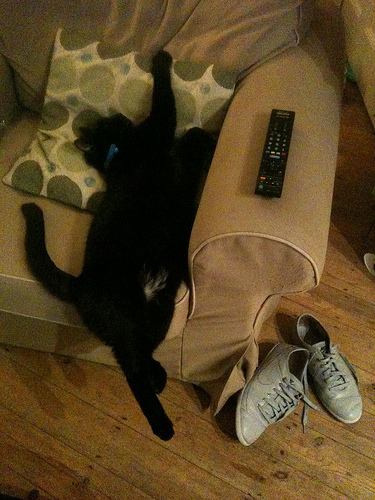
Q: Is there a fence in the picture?
A: No, there are no fences.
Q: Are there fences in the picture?
A: No, there are no fences.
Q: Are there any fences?
A: No, there are no fences.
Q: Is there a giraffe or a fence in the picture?
A: No, there are no fences or giraffes.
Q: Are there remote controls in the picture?
A: Yes, there is a remote control.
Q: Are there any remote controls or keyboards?
A: Yes, there is a remote control.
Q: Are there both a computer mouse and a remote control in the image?
A: No, there is a remote control but no computer mice.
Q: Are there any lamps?
A: No, there are no lamps.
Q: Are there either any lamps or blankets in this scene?
A: No, there are no lamps or blankets.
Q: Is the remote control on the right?
A: Yes, the remote control is on the right of the image.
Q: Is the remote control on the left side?
A: No, the remote control is on the right of the image.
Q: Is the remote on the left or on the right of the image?
A: The remote is on the right of the image.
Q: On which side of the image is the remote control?
A: The remote control is on the right of the image.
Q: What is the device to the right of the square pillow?
A: The device is a remote control.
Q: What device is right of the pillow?
A: The device is a remote control.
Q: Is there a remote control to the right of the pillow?
A: Yes, there is a remote control to the right of the pillow.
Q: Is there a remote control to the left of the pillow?
A: No, the remote control is to the right of the pillow.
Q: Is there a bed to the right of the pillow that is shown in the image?
A: No, there is a remote control to the right of the pillow.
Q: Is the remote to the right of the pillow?
A: Yes, the remote is to the right of the pillow.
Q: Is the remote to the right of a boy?
A: No, the remote is to the right of the pillow.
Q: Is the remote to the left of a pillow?
A: No, the remote is to the right of a pillow.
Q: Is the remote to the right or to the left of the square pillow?
A: The remote is to the right of the pillow.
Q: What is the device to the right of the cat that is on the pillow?
A: The device is a remote control.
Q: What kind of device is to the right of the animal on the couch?
A: The device is a remote control.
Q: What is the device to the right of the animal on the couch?
A: The device is a remote control.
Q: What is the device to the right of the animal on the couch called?
A: The device is a remote control.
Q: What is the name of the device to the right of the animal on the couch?
A: The device is a remote control.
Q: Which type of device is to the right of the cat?
A: The device is a remote control.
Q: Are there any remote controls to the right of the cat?
A: Yes, there is a remote control to the right of the cat.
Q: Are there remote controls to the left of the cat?
A: No, the remote control is to the right of the cat.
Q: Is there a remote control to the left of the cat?
A: No, the remote control is to the right of the cat.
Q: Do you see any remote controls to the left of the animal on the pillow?
A: No, the remote control is to the right of the cat.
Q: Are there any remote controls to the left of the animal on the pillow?
A: No, the remote control is to the right of the cat.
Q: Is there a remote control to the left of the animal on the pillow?
A: No, the remote control is to the right of the cat.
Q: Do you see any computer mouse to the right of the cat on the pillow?
A: No, there is a remote control to the right of the cat.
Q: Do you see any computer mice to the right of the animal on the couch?
A: No, there is a remote control to the right of the cat.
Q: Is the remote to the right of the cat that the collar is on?
A: Yes, the remote is to the right of the cat.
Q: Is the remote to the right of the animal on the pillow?
A: Yes, the remote is to the right of the cat.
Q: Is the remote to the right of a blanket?
A: No, the remote is to the right of the cat.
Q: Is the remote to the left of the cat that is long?
A: No, the remote is to the right of the cat.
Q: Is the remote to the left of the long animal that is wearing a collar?
A: No, the remote is to the right of the cat.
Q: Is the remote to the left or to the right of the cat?
A: The remote is to the right of the cat.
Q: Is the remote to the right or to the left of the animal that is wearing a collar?
A: The remote is to the right of the cat.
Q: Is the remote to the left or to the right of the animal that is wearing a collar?
A: The remote is to the right of the cat.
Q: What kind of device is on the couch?
A: The device is a remote control.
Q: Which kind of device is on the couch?
A: The device is a remote control.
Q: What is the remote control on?
A: The remote control is on the couch.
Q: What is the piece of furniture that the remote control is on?
A: The piece of furniture is a couch.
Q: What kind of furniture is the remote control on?
A: The remote control is on the couch.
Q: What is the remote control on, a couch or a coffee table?
A: The remote control is on a couch.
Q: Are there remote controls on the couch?
A: Yes, there is a remote control on the couch.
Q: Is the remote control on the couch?
A: Yes, the remote control is on the couch.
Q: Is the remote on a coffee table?
A: No, the remote is on the couch.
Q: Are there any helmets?
A: No, there are no helmets.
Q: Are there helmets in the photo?
A: No, there are no helmets.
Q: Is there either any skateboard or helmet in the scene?
A: No, there are no helmets or skateboards.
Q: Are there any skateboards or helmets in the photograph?
A: No, there are no helmets or skateboards.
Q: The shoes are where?
A: The shoes are on the floor.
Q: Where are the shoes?
A: The shoes are on the floor.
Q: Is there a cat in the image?
A: Yes, there is a cat.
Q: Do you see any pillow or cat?
A: Yes, there is a cat.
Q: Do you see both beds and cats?
A: No, there is a cat but no beds.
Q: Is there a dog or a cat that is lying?
A: Yes, the cat is lying.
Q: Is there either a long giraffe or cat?
A: Yes, there is a long cat.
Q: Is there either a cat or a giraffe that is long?
A: Yes, the cat is long.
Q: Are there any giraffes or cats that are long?
A: Yes, the cat is long.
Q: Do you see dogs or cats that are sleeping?
A: Yes, the cat is sleeping.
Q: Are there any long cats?
A: Yes, there is a long cat.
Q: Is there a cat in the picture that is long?
A: Yes, there is a cat that is long.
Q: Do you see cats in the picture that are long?
A: Yes, there is a cat that is long.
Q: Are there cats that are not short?
A: Yes, there is a long cat.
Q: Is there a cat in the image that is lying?
A: Yes, there is a cat that is lying.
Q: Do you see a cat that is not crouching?
A: Yes, there is a cat that is lying .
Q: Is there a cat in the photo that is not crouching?
A: Yes, there is a cat that is lying.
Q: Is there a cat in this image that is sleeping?
A: Yes, there is a cat that is sleeping.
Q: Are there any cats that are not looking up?
A: Yes, there is a cat that is sleeping.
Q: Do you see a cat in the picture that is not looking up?
A: Yes, there is a cat that is sleeping .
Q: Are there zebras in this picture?
A: No, there are no zebras.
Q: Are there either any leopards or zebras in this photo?
A: No, there are no zebras or leopards.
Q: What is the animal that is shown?
A: The animal is a cat.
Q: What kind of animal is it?
A: The animal is a cat.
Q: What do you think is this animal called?
A: This is a cat.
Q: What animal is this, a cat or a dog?
A: This is a cat.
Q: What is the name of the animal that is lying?
A: The animal is a cat.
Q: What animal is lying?
A: The animal is a cat.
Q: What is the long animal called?
A: The animal is a cat.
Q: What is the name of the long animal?
A: The animal is a cat.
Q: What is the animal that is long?
A: The animal is a cat.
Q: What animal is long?
A: The animal is a cat.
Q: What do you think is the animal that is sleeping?
A: The animal is a cat.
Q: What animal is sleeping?
A: The animal is a cat.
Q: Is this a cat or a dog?
A: This is a cat.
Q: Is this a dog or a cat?
A: This is a cat.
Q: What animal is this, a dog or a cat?
A: This is a cat.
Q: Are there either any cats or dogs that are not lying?
A: No, there is a cat but it is lying.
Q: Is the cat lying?
A: Yes, the cat is lying.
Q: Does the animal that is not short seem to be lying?
A: Yes, the cat is lying.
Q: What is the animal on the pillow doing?
A: The cat is lying.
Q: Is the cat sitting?
A: No, the cat is lying.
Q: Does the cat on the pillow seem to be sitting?
A: No, the cat is lying.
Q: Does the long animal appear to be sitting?
A: No, the cat is lying.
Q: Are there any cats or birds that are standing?
A: No, there is a cat but it is lying.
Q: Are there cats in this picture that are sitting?
A: No, there is a cat but it is lying.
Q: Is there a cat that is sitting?
A: No, there is a cat but it is lying.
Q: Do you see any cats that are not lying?
A: No, there is a cat but it is lying.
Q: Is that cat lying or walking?
A: The cat is lying.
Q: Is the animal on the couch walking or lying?
A: The cat is lying.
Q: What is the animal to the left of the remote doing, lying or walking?
A: The cat is lying.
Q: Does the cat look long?
A: Yes, the cat is long.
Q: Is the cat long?
A: Yes, the cat is long.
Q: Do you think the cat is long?
A: Yes, the cat is long.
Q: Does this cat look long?
A: Yes, the cat is long.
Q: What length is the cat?
A: The cat is long.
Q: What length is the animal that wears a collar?
A: The cat is long.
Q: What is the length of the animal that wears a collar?
A: The cat is long.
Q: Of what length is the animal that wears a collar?
A: The cat is long.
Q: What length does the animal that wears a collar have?
A: The cat has long length.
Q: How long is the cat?
A: The cat is long.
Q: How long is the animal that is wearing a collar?
A: The cat is long.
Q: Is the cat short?
A: No, the cat is long.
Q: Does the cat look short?
A: No, the cat is long.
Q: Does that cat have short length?
A: No, the cat is long.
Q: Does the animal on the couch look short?
A: No, the cat is long.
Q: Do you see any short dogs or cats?
A: No, there is a cat but it is long.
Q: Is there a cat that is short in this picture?
A: No, there is a cat but it is long.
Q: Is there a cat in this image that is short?
A: No, there is a cat but it is long.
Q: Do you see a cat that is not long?
A: No, there is a cat but it is long.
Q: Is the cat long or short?
A: The cat is long.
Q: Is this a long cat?
A: Yes, this is a long cat.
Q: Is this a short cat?
A: No, this is a long cat.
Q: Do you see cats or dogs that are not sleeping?
A: No, there is a cat but it is sleeping.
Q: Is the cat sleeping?
A: Yes, the cat is sleeping.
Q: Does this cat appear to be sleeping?
A: Yes, the cat is sleeping.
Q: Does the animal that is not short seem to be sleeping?
A: Yes, the cat is sleeping.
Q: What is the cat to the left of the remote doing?
A: The cat is sleeping.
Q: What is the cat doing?
A: The cat is sleeping.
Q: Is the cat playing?
A: No, the cat is sleeping.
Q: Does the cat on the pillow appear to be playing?
A: No, the cat is sleeping.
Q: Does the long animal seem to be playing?
A: No, the cat is sleeping.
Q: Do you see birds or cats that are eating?
A: No, there is a cat but it is sleeping.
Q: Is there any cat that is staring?
A: No, there is a cat but it is sleeping.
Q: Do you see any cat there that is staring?
A: No, there is a cat but it is sleeping.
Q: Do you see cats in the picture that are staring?
A: No, there is a cat but it is sleeping.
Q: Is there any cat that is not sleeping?
A: No, there is a cat but it is sleeping.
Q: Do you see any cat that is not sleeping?
A: No, there is a cat but it is sleeping.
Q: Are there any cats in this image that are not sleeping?
A: No, there is a cat but it is sleeping.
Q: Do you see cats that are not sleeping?
A: No, there is a cat but it is sleeping.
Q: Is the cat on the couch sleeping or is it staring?
A: The cat is sleeping.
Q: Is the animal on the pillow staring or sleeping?
A: The cat is sleeping.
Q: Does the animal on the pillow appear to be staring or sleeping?
A: The cat is sleeping.